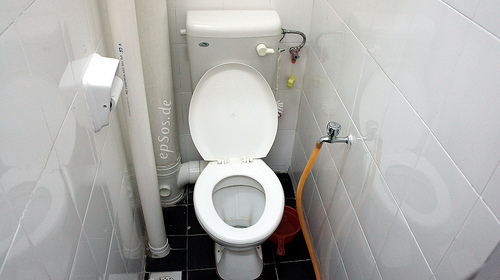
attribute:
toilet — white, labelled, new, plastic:
[179, 8, 284, 280]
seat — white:
[193, 162, 286, 241]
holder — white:
[82, 44, 128, 137]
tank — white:
[180, 5, 283, 71]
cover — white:
[183, 5, 280, 38]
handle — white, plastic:
[257, 37, 278, 62]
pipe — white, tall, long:
[107, 0, 185, 251]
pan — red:
[270, 203, 303, 259]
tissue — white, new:
[108, 76, 128, 114]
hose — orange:
[295, 142, 323, 279]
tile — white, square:
[17, 2, 79, 146]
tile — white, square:
[2, 23, 54, 219]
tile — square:
[22, 148, 84, 279]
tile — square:
[55, 88, 100, 227]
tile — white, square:
[371, 85, 429, 207]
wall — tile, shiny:
[289, 0, 498, 276]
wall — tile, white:
[1, 2, 154, 280]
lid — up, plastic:
[189, 61, 278, 158]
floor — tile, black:
[145, 169, 316, 278]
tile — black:
[163, 203, 188, 236]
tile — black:
[144, 234, 187, 270]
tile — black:
[186, 204, 211, 233]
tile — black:
[186, 233, 218, 267]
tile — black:
[187, 269, 226, 277]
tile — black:
[277, 174, 295, 196]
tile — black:
[277, 260, 318, 279]